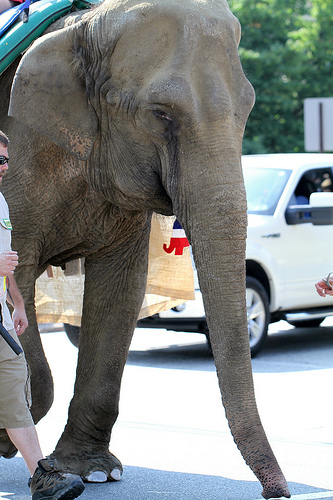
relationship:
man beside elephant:
[0, 126, 20, 306] [18, 22, 267, 252]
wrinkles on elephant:
[27, 170, 126, 265] [18, 22, 267, 252]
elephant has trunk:
[18, 22, 267, 252] [195, 188, 292, 498]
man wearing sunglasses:
[0, 126, 20, 306] [0, 153, 12, 172]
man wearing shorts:
[0, 126, 20, 306] [4, 314, 43, 434]